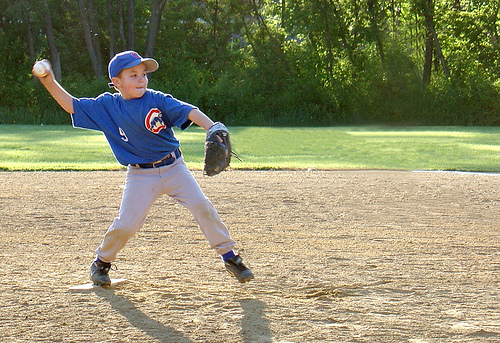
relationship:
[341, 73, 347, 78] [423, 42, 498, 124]
leaf on plant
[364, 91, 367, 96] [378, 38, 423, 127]
leaf on plant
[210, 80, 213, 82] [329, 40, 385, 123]
leaf on plant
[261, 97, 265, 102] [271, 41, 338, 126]
leaf on plant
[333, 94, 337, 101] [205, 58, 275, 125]
leaf on plant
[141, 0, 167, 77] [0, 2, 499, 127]
tree on woods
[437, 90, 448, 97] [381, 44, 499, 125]
green leaf on a plant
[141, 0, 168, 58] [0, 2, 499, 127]
tree in woods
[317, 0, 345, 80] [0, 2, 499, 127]
tree in woods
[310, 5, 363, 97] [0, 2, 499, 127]
tree in woods